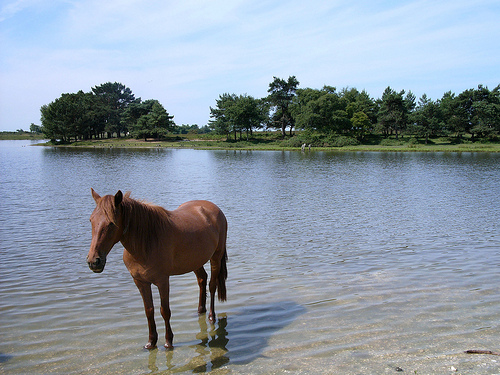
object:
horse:
[86, 188, 228, 350]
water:
[0, 138, 500, 373]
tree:
[207, 116, 230, 140]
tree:
[127, 111, 169, 141]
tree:
[92, 81, 134, 136]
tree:
[261, 74, 300, 137]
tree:
[350, 112, 373, 144]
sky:
[0, 0, 499, 132]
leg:
[152, 275, 175, 348]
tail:
[217, 221, 229, 302]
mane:
[100, 190, 169, 227]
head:
[85, 188, 126, 273]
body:
[124, 199, 227, 275]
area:
[0, 85, 498, 374]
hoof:
[208, 313, 215, 321]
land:
[28, 131, 499, 152]